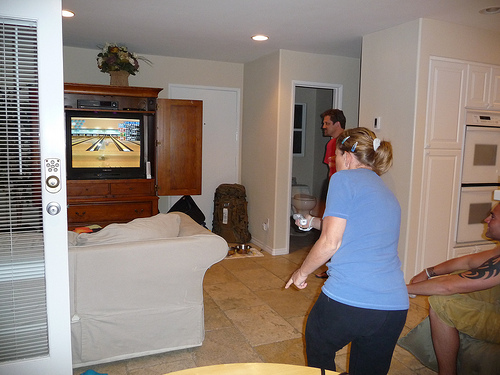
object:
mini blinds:
[0, 15, 51, 365]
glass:
[0, 100, 36, 333]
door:
[1, 1, 76, 375]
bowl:
[234, 242, 252, 255]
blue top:
[321, 167, 411, 311]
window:
[290, 102, 307, 159]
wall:
[361, 17, 424, 283]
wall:
[238, 48, 291, 257]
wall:
[63, 46, 248, 208]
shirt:
[319, 166, 410, 310]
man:
[314, 105, 350, 280]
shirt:
[323, 132, 347, 175]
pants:
[303, 290, 407, 375]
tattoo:
[457, 252, 499, 282]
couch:
[0, 205, 230, 369]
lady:
[282, 126, 410, 375]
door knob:
[46, 200, 63, 217]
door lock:
[44, 157, 62, 194]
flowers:
[93, 43, 142, 76]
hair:
[333, 126, 393, 177]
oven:
[458, 108, 499, 189]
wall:
[422, 25, 462, 138]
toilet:
[292, 190, 315, 227]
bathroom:
[286, 79, 343, 254]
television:
[64, 104, 155, 181]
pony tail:
[367, 137, 396, 176]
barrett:
[340, 135, 350, 144]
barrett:
[350, 139, 360, 152]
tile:
[217, 300, 293, 356]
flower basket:
[90, 43, 141, 89]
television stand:
[62, 82, 203, 233]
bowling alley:
[66, 115, 143, 169]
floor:
[217, 304, 291, 347]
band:
[371, 135, 381, 150]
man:
[403, 199, 499, 375]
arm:
[407, 250, 500, 296]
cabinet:
[62, 83, 203, 231]